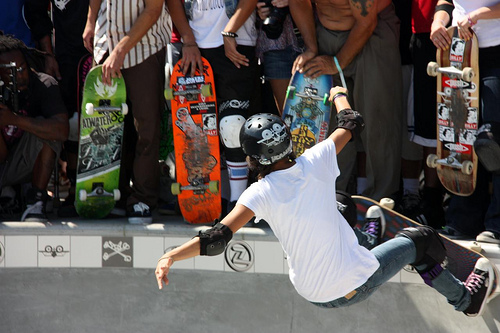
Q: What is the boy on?
A: Skateboard.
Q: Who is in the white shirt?
A: The boy.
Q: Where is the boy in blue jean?
A: The boy skating.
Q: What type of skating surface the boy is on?
A: Skating surface is concrete.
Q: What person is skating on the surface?
A: Boy with black and white helmet.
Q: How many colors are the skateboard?
A: 2.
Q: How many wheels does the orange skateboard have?
A: 4.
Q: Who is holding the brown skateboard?
A: A boy.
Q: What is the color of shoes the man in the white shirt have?
A: Black.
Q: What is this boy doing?
A: Skateboarding.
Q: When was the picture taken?
A: Daytime.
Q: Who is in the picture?
A: A boy.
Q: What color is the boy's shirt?
A: White.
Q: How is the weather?
A: Sunny.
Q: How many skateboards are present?
A: Five.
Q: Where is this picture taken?
A: In a skate park.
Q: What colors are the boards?
A: Orange, green and blue.